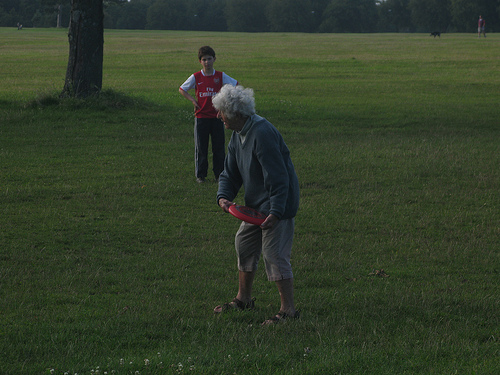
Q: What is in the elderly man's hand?
A: Frisbee.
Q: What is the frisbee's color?
A: Red.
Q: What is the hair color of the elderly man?
A: White.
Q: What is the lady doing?
A: Playing frisbee.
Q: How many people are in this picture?
A: Two.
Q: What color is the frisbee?
A: Red.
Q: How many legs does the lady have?
A: Two.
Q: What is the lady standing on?
A: Grass.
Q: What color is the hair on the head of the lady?
A: Grey.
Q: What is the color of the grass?
A: Green.